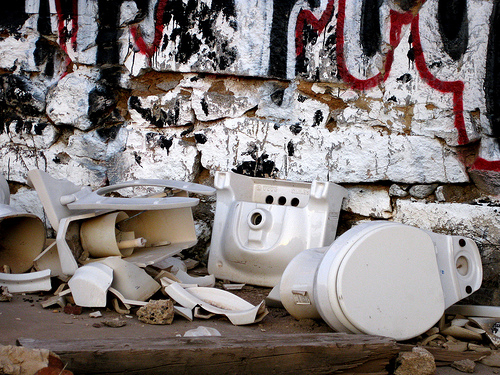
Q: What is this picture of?
A: Broken toilets.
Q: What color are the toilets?
A: White.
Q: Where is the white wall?
A: Behind the toilets.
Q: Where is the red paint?
A: On the wall.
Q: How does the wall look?
A: Painted with graffiti.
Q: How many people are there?
A: None.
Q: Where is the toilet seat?
A: On top of the pile.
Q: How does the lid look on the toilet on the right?
A: It is closed.